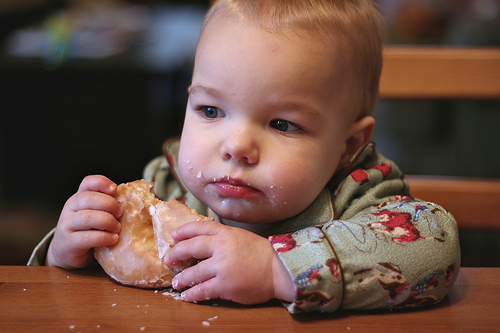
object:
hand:
[50, 172, 128, 274]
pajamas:
[23, 131, 463, 320]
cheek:
[256, 140, 332, 217]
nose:
[218, 117, 258, 166]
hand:
[163, 220, 275, 307]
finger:
[160, 234, 212, 265]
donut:
[88, 178, 212, 291]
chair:
[373, 43, 497, 266]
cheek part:
[173, 146, 207, 192]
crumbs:
[196, 319, 212, 329]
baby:
[25, 0, 460, 318]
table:
[0, 265, 499, 332]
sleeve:
[266, 166, 462, 317]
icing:
[266, 182, 274, 190]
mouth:
[202, 173, 263, 200]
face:
[175, 12, 347, 223]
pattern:
[366, 207, 426, 245]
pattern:
[350, 259, 411, 310]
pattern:
[287, 263, 339, 319]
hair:
[193, 1, 387, 119]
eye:
[194, 103, 228, 121]